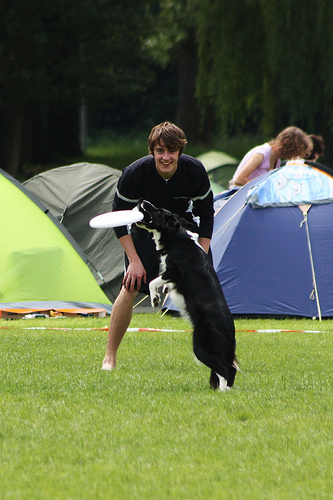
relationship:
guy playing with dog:
[67, 106, 258, 369] [130, 191, 243, 395]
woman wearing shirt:
[227, 120, 316, 194] [227, 138, 286, 193]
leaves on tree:
[193, 10, 319, 122] [189, 14, 329, 141]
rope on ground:
[0, 324, 332, 333] [4, 299, 318, 496]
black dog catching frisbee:
[120, 193, 251, 426] [87, 203, 148, 236]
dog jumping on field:
[126, 200, 249, 396] [1, 300, 321, 490]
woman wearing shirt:
[228, 125, 311, 192] [228, 141, 280, 188]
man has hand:
[140, 123, 193, 187] [123, 260, 152, 290]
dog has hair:
[102, 185, 210, 260] [142, 203, 238, 382]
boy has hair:
[94, 119, 215, 373] [142, 119, 188, 150]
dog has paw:
[126, 200, 249, 396] [151, 293, 161, 309]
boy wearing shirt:
[98, 119, 226, 368] [111, 152, 214, 239]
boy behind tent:
[229, 123, 311, 189] [155, 159, 332, 320]